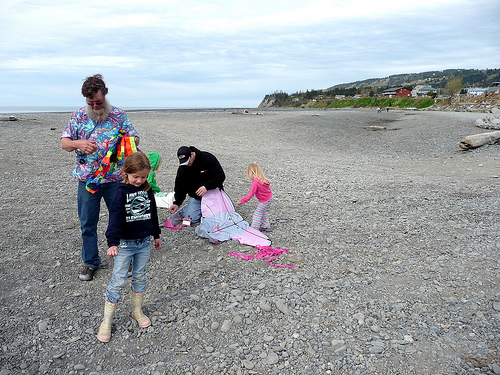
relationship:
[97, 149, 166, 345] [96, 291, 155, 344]
girl wearing boots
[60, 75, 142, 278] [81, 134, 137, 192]
man holding kite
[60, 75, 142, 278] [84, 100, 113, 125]
man with beard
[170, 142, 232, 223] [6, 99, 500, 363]
man on ground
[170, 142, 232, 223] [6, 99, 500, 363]
man kneeling on ground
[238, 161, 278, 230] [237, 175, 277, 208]
girl in pink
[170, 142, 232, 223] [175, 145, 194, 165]
man in basball hat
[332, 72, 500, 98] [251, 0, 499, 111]
houses in back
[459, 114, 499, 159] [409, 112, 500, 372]
logs on side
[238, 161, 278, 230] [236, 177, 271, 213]
girl in shirt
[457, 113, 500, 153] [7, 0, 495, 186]
piece in background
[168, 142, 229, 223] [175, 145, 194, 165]
man wearing basball hat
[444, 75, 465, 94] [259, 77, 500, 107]
tree on slope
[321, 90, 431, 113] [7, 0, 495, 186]
patch in background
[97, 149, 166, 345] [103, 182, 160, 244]
girl with shirt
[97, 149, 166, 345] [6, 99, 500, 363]
girl looking at ground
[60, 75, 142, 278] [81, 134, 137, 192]
man looking at kite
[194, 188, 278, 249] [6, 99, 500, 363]
kite on ground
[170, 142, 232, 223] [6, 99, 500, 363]
man looking at ground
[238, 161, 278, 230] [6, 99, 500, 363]
girl looking at ground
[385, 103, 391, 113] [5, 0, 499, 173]
person in distance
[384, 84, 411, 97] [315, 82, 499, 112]
building on hill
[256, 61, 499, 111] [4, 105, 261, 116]
cliff over ocean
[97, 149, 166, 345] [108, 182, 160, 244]
girl wearing shirt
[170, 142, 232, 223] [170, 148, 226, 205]
man with shirt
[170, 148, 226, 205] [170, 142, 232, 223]
shirt on man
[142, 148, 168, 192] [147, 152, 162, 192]
child in sweatshirt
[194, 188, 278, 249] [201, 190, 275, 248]
kite shaped like elephant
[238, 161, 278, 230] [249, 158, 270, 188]
girl with hair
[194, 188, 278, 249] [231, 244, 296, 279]
kite has tassels